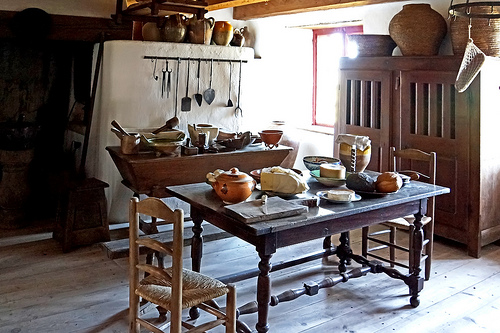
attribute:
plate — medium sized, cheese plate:
[316, 187, 362, 204]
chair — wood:
[127, 185, 272, 328]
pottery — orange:
[212, 167, 257, 203]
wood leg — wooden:
[410, 218, 422, 305]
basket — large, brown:
[387, 2, 447, 55]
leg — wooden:
[403, 211, 425, 309]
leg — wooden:
[335, 230, 352, 284]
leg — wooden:
[251, 250, 278, 332]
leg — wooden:
[188, 220, 208, 272]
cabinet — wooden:
[329, 55, 499, 257]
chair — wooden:
[87, 183, 244, 322]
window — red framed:
[308, 25, 363, 130]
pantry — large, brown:
[328, 53, 498, 260]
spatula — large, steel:
[180, 53, 192, 114]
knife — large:
[257, 192, 267, 219]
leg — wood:
[408, 207, 423, 307]